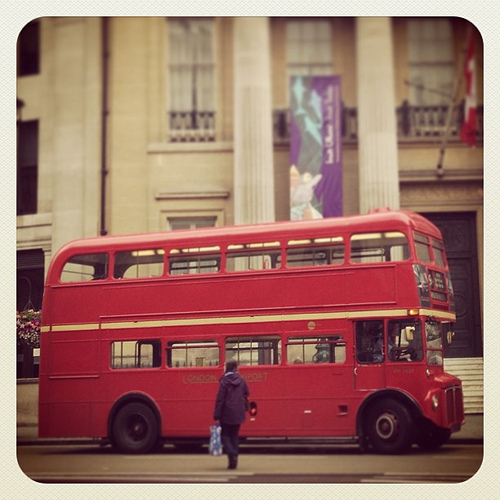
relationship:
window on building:
[162, 16, 221, 154] [105, 17, 481, 441]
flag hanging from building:
[285, 72, 347, 218] [105, 17, 481, 441]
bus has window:
[31, 203, 467, 458] [343, 228, 406, 267]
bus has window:
[31, 203, 467, 458] [49, 247, 112, 281]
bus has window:
[31, 203, 467, 458] [218, 238, 274, 276]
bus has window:
[31, 203, 467, 458] [211, 338, 280, 366]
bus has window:
[31, 203, 467, 458] [108, 334, 158, 374]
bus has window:
[31, 203, 467, 458] [47, 251, 101, 281]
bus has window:
[31, 203, 467, 458] [108, 245, 167, 281]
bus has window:
[31, 203, 467, 458] [166, 242, 219, 278]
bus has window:
[31, 203, 467, 458] [214, 235, 283, 277]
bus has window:
[31, 203, 467, 458] [279, 233, 350, 275]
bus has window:
[31, 203, 467, 458] [344, 225, 414, 268]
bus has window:
[31, 203, 467, 458] [102, 336, 162, 372]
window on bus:
[159, 336, 218, 369] [31, 203, 467, 458]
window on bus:
[216, 333, 283, 373] [31, 203, 467, 458]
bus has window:
[31, 203, 467, 458] [272, 333, 351, 369]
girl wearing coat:
[212, 359, 251, 471] [213, 371, 251, 426]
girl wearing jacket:
[211, 361, 255, 472] [206, 369, 261, 436]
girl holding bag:
[212, 359, 251, 471] [207, 408, 237, 466]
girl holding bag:
[212, 359, 251, 471] [202, 421, 239, 460]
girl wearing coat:
[212, 359, 251, 471] [212, 370, 258, 432]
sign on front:
[427, 264, 454, 300] [392, 203, 486, 443]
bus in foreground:
[31, 203, 467, 458] [12, 16, 487, 490]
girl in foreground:
[212, 359, 251, 471] [12, 16, 487, 490]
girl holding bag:
[212, 359, 251, 471] [200, 408, 233, 468]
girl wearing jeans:
[212, 359, 251, 471] [221, 421, 253, 480]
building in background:
[15, 15, 479, 426] [19, 23, 489, 282]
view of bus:
[40, 205, 468, 465] [31, 203, 467, 458]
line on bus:
[39, 305, 466, 339] [31, 203, 467, 458]